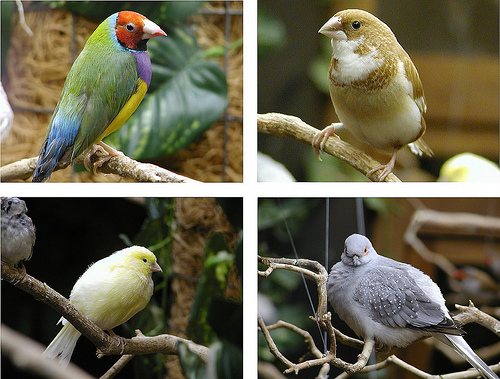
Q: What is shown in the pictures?
A: Birds.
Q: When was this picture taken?
A: During the day.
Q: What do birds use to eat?
A: Their beaks.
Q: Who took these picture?
A: A person.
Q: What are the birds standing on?
A: Branches.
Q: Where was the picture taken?
A: The outdoors.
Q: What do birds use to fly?
A: Their wings.